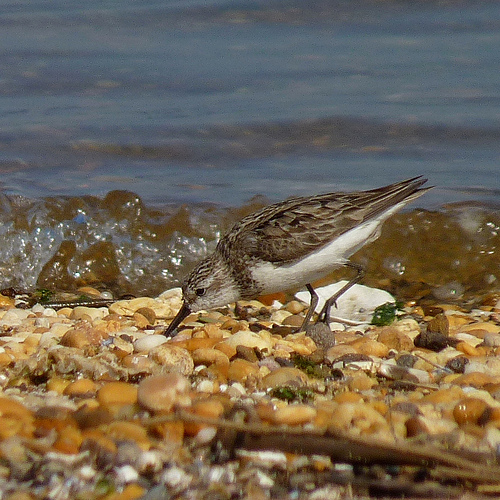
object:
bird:
[163, 172, 439, 339]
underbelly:
[252, 218, 384, 297]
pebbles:
[58, 325, 86, 350]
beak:
[161, 302, 192, 337]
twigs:
[370, 442, 392, 452]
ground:
[0, 287, 500, 499]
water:
[0, 0, 500, 292]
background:
[0, 0, 498, 317]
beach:
[0, 113, 500, 500]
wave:
[0, 186, 500, 299]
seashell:
[294, 279, 397, 327]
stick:
[140, 407, 500, 499]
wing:
[246, 173, 430, 265]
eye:
[195, 287, 206, 296]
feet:
[292, 282, 319, 335]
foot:
[313, 259, 367, 330]